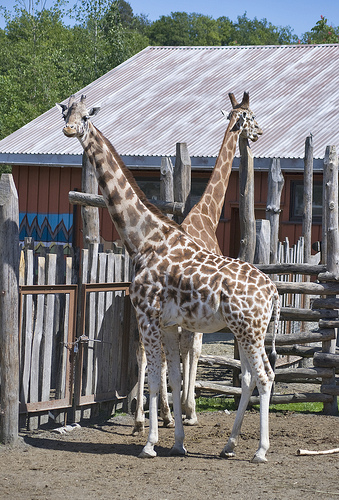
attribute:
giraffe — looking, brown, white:
[44, 87, 282, 465]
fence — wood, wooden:
[6, 246, 325, 421]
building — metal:
[3, 34, 332, 288]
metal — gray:
[9, 41, 338, 167]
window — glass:
[289, 177, 329, 225]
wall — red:
[16, 170, 96, 216]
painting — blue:
[23, 207, 77, 239]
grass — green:
[276, 398, 327, 415]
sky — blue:
[2, 4, 335, 23]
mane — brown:
[93, 121, 188, 237]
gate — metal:
[15, 280, 141, 420]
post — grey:
[2, 168, 24, 446]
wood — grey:
[299, 130, 321, 258]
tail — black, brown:
[269, 286, 280, 365]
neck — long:
[81, 123, 160, 247]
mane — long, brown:
[190, 125, 245, 230]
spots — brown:
[111, 197, 249, 317]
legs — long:
[131, 318, 283, 469]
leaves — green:
[16, 48, 49, 89]